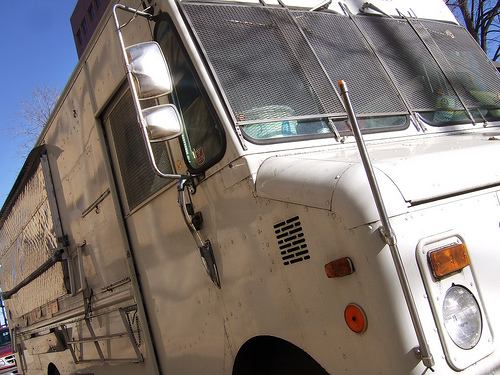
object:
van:
[0, 0, 499, 374]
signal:
[322, 257, 353, 279]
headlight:
[440, 284, 482, 351]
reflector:
[343, 301, 367, 337]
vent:
[271, 215, 311, 266]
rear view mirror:
[137, 103, 184, 144]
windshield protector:
[177, 0, 403, 126]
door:
[88, 75, 227, 374]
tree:
[440, 2, 500, 62]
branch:
[479, 2, 500, 55]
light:
[427, 242, 472, 282]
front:
[258, 125, 499, 374]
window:
[153, 17, 223, 172]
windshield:
[179, 0, 409, 146]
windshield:
[352, 13, 499, 126]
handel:
[174, 175, 222, 289]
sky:
[1, 0, 499, 211]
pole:
[337, 79, 434, 371]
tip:
[337, 78, 345, 85]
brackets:
[380, 226, 397, 247]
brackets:
[415, 346, 430, 357]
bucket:
[239, 105, 299, 139]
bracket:
[182, 169, 196, 195]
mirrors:
[121, 42, 174, 102]